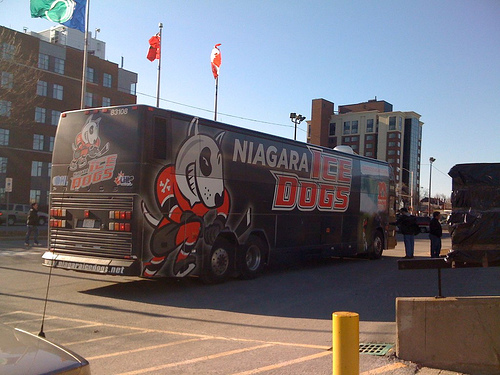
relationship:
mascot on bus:
[140, 117, 231, 277] [42, 109, 395, 281]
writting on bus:
[232, 137, 352, 211] [42, 109, 395, 281]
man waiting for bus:
[398, 206, 422, 261] [42, 109, 395, 281]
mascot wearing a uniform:
[140, 117, 231, 277] [155, 166, 229, 252]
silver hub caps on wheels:
[210, 246, 228, 275] [207, 236, 236, 285]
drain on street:
[360, 339, 395, 361] [89, 280, 333, 372]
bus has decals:
[42, 109, 395, 281] [140, 117, 231, 277]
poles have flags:
[81, 0, 90, 108] [30, 0, 90, 29]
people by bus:
[398, 206, 422, 261] [42, 109, 395, 281]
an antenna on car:
[39, 165, 70, 339] [1, 321, 90, 373]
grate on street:
[360, 339, 391, 359] [89, 280, 333, 372]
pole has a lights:
[294, 122, 297, 142] [289, 112, 306, 124]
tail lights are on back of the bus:
[107, 210, 134, 234] [44, 108, 143, 268]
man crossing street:
[24, 199, 43, 248] [89, 280, 333, 372]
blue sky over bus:
[222, 2, 499, 95] [42, 109, 395, 281]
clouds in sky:
[281, 23, 387, 83] [247, 41, 347, 102]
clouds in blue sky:
[281, 23, 387, 83] [222, 2, 499, 95]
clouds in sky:
[281, 23, 387, 83] [222, 2, 499, 95]